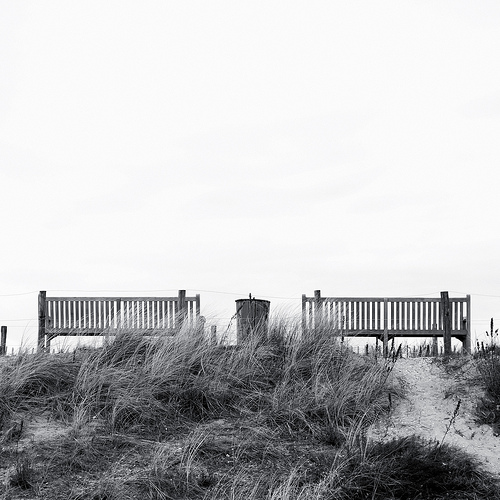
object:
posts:
[305, 292, 453, 353]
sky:
[0, 0, 495, 360]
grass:
[1, 307, 498, 498]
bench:
[38, 290, 470, 354]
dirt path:
[356, 338, 498, 484]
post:
[442, 291, 452, 356]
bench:
[298, 291, 477, 349]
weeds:
[32, 288, 474, 357]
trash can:
[234, 295, 272, 346]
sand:
[369, 357, 499, 476]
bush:
[474, 337, 499, 425]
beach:
[0, 350, 496, 498]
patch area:
[378, 353, 499, 471]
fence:
[37, 288, 201, 354]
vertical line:
[84, 301, 94, 328]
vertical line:
[163, 301, 169, 324]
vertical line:
[59, 300, 64, 327]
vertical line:
[110, 302, 115, 324]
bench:
[35, 290, 202, 353]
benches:
[31, 287, 473, 360]